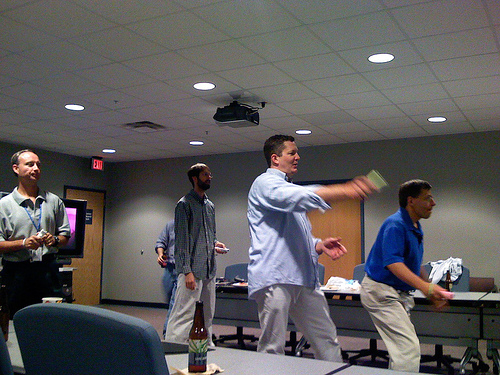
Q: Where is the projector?
A: On the ceiling.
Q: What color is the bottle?
A: Brown.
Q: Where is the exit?
A: Left.